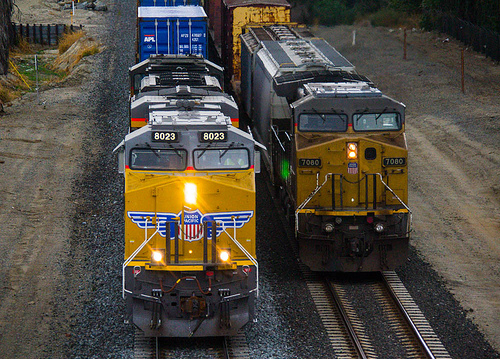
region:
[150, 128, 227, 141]
The number 8023 twice on a yellow train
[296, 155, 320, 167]
The number 7080 on the left side of a yellow train.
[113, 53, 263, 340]
Bright yellow train with number 8023 on the first car.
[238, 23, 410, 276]
First car of the 7080 train that is yellow and grey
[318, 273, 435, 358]
Brass shiny tracks in front of the 7080 train.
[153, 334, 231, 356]
Brown tracks in front of the 8023 train.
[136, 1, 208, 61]
Bright blue cars behind the 8023 train.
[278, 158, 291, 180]
Green ball of light on the left side of the 7080 train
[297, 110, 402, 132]
Two front rectangle shaped windows on the 7080 train.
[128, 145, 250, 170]
Two rectangle windows on the front of the 8023 train.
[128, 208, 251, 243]
Union Pacific logo on the front of the train on the left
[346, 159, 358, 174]
Tiny Union Pacific logo on the front of the train on the right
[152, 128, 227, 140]
The two numbers "8023" on at the top of the train on the left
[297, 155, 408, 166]
The numbers "7080" about midway down on the front of the train on the right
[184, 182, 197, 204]
The large light in the middle of the front of the train on the left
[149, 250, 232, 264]
Two small lights near the bottom of the front of the train on the left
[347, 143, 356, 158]
The duel light in the middle of the front of the train on the right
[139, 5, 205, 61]
The blue "APL" container being pulled by the train on the left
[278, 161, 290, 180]
The green glow on the left side of the train on the right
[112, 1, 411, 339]
Two modern freight trains running parallel to each other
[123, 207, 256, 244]
the Union Pacific logo on a train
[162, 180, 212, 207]
the front headlight on a train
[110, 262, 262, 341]
a cowcatcher on the front of a train engine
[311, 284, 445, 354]
a section of train tracks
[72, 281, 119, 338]
gravel beside train tracks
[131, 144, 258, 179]
windows on the front of a train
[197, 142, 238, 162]
windshield wipers on the front windshield of a train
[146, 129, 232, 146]
identification numbers on a train engine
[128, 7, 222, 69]
a blue railroad car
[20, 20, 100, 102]
debris near the side of railroad tracks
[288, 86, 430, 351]
train engine on tracks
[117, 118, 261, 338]
front of yellow train engine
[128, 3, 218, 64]
blue boxcar of train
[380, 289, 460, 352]
train track and stones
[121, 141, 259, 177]
windshield of a train engine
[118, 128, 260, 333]
train engine with lights on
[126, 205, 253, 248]
logo with blue wings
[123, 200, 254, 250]
red white and blue logo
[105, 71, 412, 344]
two yellow train engines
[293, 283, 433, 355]
train tracks and ties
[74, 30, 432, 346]
the yellow fronts of two train engines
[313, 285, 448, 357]
metal train tracks on the ground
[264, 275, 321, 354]
grey and black gravel on the ground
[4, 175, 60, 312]
brown dirt ground next to the train tracks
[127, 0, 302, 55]
blue and yellow shipping containers being pulled by the trains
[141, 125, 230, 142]
white numbers on the front of the train on the left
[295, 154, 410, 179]
white numbers on the front of the train on the left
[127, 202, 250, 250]
red, white, and blue logo on the front of the train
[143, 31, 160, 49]
white logo on the blue shipping container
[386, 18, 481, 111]
rusted metal posts in the ground